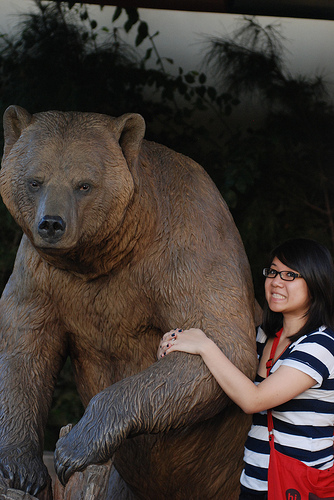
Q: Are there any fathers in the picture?
A: No, there are no fathers.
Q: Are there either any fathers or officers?
A: No, there are no fathers or officers.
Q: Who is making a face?
A: The girl is making a face.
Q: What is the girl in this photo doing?
A: The girl is making a face.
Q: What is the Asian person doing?
A: The girl is making a face.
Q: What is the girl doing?
A: The girl is making a face.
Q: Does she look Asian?
A: Yes, the girl is asian.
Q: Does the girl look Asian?
A: Yes, the girl is asian.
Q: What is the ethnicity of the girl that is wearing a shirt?
A: The girl is asian.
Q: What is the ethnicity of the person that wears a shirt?
A: The girl is asian.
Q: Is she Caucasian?
A: No, the girl is asian.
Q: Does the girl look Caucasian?
A: No, the girl is asian.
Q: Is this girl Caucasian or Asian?
A: The girl is asian.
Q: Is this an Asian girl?
A: Yes, this is an Asian girl.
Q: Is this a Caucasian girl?
A: No, this is an Asian girl.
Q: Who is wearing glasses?
A: The girl is wearing glasses.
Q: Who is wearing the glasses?
A: The girl is wearing glasses.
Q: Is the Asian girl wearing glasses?
A: Yes, the girl is wearing glasses.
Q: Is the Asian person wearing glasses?
A: Yes, the girl is wearing glasses.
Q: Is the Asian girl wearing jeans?
A: No, the girl is wearing glasses.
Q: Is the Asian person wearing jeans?
A: No, the girl is wearing glasses.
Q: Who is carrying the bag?
A: The girl is carrying the bag.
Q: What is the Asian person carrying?
A: The girl is carrying a bag.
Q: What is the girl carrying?
A: The girl is carrying a bag.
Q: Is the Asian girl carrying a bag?
A: Yes, the girl is carrying a bag.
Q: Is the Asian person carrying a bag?
A: Yes, the girl is carrying a bag.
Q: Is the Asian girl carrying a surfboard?
A: No, the girl is carrying a bag.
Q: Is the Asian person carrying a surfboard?
A: No, the girl is carrying a bag.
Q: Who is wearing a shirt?
A: The girl is wearing a shirt.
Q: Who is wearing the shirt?
A: The girl is wearing a shirt.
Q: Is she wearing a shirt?
A: Yes, the girl is wearing a shirt.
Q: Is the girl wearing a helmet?
A: No, the girl is wearing a shirt.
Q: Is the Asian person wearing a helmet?
A: No, the girl is wearing a shirt.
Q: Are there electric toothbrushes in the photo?
A: No, there are no electric toothbrushes.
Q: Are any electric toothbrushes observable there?
A: No, there are no electric toothbrushes.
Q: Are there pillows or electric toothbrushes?
A: No, there are no electric toothbrushes or pillows.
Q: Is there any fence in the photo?
A: No, there are no fences.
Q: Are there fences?
A: No, there are no fences.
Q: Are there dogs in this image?
A: No, there are no dogs.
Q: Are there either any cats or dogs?
A: No, there are no dogs or cats.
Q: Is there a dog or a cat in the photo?
A: No, there are no dogs or cats.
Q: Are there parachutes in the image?
A: No, there are no parachutes.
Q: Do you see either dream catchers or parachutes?
A: No, there are no parachutes or dream catchers.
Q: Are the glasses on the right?
A: Yes, the glasses are on the right of the image.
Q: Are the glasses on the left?
A: No, the glasses are on the right of the image.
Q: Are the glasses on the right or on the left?
A: The glasses are on the right of the image.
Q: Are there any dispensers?
A: No, there are no dispensers.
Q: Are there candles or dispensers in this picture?
A: No, there are no dispensers or candles.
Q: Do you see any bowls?
A: No, there are no bowls.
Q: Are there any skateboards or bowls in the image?
A: No, there are no bowls or skateboards.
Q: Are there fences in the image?
A: No, there are no fences.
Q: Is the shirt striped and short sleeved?
A: Yes, the shirt is striped and short sleeved.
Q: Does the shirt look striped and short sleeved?
A: Yes, the shirt is striped and short sleeved.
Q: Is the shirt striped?
A: Yes, the shirt is striped.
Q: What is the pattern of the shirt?
A: The shirt is striped.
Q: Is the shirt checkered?
A: No, the shirt is striped.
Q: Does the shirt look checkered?
A: No, the shirt is striped.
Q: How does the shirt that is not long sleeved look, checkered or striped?
A: The shirt is striped.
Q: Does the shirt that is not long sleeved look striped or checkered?
A: The shirt is striped.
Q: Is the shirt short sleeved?
A: Yes, the shirt is short sleeved.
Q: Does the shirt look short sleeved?
A: Yes, the shirt is short sleeved.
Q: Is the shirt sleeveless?
A: No, the shirt is short sleeved.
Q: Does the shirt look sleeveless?
A: No, the shirt is short sleeved.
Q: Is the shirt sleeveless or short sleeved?
A: The shirt is short sleeved.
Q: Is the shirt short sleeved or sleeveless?
A: The shirt is short sleeved.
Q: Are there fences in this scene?
A: No, there are no fences.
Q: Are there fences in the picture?
A: No, there are no fences.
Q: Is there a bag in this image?
A: Yes, there is a bag.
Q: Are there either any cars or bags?
A: Yes, there is a bag.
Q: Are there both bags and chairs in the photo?
A: No, there is a bag but no chairs.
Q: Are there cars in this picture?
A: No, there are no cars.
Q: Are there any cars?
A: No, there are no cars.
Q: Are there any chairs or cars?
A: No, there are no cars or chairs.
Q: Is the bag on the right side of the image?
A: Yes, the bag is on the right of the image.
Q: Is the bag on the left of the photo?
A: No, the bag is on the right of the image.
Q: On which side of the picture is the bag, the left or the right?
A: The bag is on the right of the image.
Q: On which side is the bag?
A: The bag is on the right of the image.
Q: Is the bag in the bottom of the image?
A: Yes, the bag is in the bottom of the image.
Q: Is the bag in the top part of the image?
A: No, the bag is in the bottom of the image.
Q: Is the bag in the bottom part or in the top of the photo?
A: The bag is in the bottom of the image.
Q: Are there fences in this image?
A: No, there are no fences.